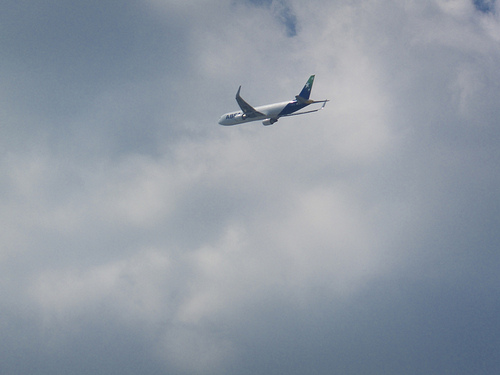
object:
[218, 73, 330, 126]
airplane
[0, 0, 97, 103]
clouds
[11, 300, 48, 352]
clouds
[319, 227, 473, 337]
cloud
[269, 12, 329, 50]
blue part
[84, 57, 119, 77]
sky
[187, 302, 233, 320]
white clouds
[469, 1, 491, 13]
blue sky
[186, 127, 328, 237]
clouds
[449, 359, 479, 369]
sky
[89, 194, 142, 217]
cloudy sky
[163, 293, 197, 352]
clouds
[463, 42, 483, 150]
clouds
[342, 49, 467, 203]
clouds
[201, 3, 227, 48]
sky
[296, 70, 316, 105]
tail